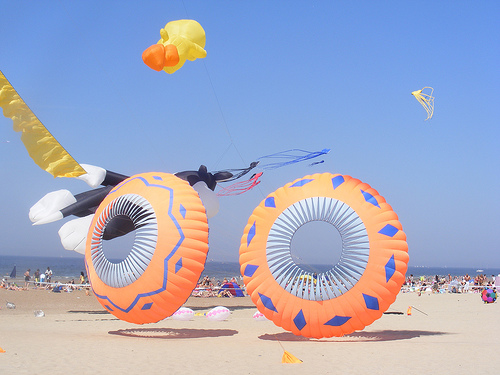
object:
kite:
[409, 85, 438, 123]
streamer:
[264, 148, 311, 158]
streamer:
[267, 160, 311, 166]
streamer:
[237, 183, 257, 194]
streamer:
[222, 183, 247, 191]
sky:
[338, 1, 499, 59]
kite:
[239, 168, 406, 330]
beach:
[212, 365, 302, 372]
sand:
[438, 342, 500, 370]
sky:
[249, 46, 377, 131]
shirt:
[44, 269, 53, 278]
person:
[44, 263, 53, 284]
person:
[24, 269, 33, 283]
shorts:
[24, 277, 31, 284]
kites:
[80, 171, 212, 325]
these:
[74, 170, 425, 337]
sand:
[207, 337, 269, 373]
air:
[138, 15, 213, 76]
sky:
[40, 6, 90, 78]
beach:
[424, 272, 494, 294]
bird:
[137, 12, 207, 73]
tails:
[424, 80, 435, 126]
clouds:
[442, 172, 493, 211]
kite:
[234, 159, 420, 348]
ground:
[333, 343, 431, 360]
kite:
[256, 145, 331, 169]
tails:
[262, 145, 318, 171]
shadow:
[104, 322, 243, 340]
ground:
[82, 333, 176, 364]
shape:
[359, 290, 383, 314]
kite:
[235, 166, 407, 333]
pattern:
[296, 200, 327, 219]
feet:
[139, 41, 181, 73]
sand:
[27, 327, 234, 360]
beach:
[447, 334, 498, 373]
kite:
[0, 70, 274, 256]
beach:
[2, 328, 76, 374]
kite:
[237, 171, 409, 339]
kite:
[84, 173, 211, 325]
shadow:
[256, 329, 454, 344]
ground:
[419, 297, 480, 319]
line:
[270, 289, 290, 338]